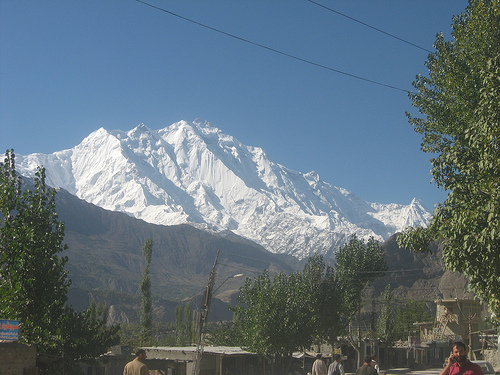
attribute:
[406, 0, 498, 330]
tree — tall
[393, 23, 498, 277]
tree — tall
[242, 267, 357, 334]
trees — small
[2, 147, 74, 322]
tree — tall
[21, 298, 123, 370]
tree — tall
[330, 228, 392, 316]
tree — tall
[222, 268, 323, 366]
tree — tall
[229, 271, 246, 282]
light — off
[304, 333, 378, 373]
people — standing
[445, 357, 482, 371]
shirt — red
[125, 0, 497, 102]
lines — power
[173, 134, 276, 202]
snow — white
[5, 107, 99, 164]
cloud — white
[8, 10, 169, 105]
sky — blue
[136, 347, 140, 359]
hair — short